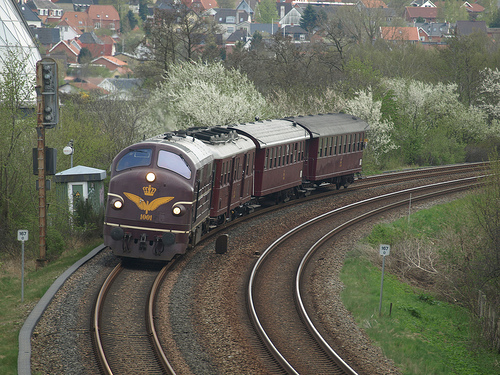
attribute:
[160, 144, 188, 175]
window — glass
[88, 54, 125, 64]
roof — orange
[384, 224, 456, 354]
grass — fresh, green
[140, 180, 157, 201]
crown — golden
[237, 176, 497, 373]
tracks — silver, curved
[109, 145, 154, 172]
window — glass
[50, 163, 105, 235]
building — tiny, green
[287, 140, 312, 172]
window — glass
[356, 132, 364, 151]
window — glass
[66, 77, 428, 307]
train — red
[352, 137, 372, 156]
window — glass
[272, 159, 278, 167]
window — glass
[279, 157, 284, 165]
window — glass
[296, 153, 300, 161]
window — glass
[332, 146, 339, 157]
window — glass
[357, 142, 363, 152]
window — glass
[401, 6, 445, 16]
rooftop — red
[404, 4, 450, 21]
house — small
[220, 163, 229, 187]
window — glass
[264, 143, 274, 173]
window — glass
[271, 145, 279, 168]
window — glass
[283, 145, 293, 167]
window — glass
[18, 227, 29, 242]
sign — white, small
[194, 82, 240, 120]
blossoms — white